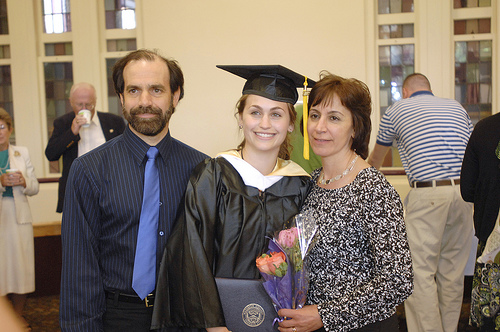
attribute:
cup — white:
[76, 108, 93, 129]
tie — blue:
[132, 142, 160, 301]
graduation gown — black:
[150, 153, 311, 332]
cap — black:
[215, 65, 318, 161]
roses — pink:
[254, 226, 310, 315]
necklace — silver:
[317, 152, 361, 188]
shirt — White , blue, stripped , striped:
[376, 90, 475, 183]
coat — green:
[1, 147, 12, 195]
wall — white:
[0, 1, 499, 228]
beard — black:
[120, 102, 174, 135]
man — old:
[46, 82, 126, 217]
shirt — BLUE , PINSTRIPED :
[59, 126, 210, 332]